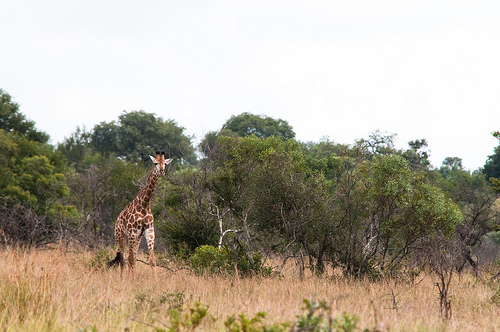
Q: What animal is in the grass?
A: Giraffe.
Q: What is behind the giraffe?
A: Trees.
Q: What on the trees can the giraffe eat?
A: Leaves.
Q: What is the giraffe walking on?
A: The giraffe is walking on a field of dry grass.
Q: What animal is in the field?
A: A giraffe is in the field.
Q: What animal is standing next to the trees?
A: A giraffe is standing next to the trees.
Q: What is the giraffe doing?
A: The giraffe is walking around in the field.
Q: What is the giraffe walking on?
A: The giraffe is walking around a field of dry grass.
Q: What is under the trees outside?
A: A field of dry grass.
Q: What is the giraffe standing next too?
A: A forest of thick trees.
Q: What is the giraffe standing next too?
A: A group of trees.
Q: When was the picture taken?
A: During the day.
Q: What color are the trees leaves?
A: Green.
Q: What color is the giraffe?
A: Brown.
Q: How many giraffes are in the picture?
A: One.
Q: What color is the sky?
A: Grey.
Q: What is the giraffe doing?
A: Walking.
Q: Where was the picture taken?
A: In a field.